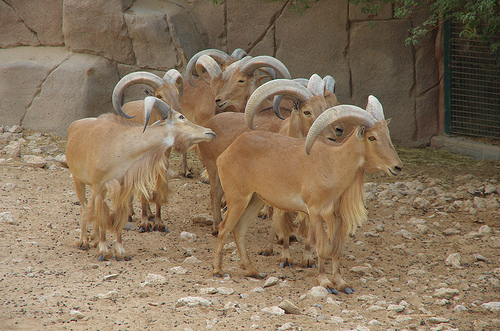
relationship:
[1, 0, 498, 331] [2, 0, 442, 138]
animal enclosure has wall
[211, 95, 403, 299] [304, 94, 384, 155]
goat has horns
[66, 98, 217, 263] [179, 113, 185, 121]
goat has eye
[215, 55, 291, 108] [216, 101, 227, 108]
goat has mouth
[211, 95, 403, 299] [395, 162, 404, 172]
goat has nose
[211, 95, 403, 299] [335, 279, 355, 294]
goat has foot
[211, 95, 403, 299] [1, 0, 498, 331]
goat in animal enclosure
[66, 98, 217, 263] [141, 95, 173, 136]
goat has horns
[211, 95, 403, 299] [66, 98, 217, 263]
goat beside goat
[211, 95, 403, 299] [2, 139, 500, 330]
goat on ground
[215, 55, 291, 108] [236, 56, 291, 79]
goat has horns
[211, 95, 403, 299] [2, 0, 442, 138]
goat in front of wall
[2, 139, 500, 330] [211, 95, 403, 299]
ground under goat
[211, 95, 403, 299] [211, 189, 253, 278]
goat has leg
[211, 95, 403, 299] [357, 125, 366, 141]
goat has ear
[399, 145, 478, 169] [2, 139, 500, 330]
hay on ground